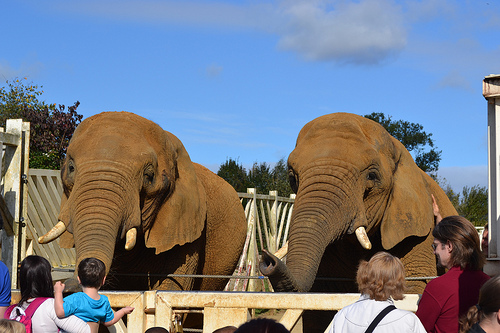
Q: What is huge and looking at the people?
A: The head of an elephant.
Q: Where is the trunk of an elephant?
A: Pointing at people.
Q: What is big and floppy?
A: The ear of an elephant.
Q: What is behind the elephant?
A: A green leafy tree.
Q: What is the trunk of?
A: Brown elephant.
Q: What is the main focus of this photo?
A: Two adult elephants standing side by side.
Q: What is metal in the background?
A: Fence with diagonal slats.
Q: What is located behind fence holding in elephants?
A: Trees.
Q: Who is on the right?
A: Man wearing glasses and a maroon colored shirt.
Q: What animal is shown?
A: Elephant.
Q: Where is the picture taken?
A: Zoo.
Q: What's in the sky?
A: Clouds.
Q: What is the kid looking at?
A: Elephants.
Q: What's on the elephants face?
A: Husks.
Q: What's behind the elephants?
A: Fence.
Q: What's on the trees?
A: Leaves.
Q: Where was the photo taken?
A: The zoo.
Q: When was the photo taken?
A: Day time.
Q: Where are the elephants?
A: At the zoo.